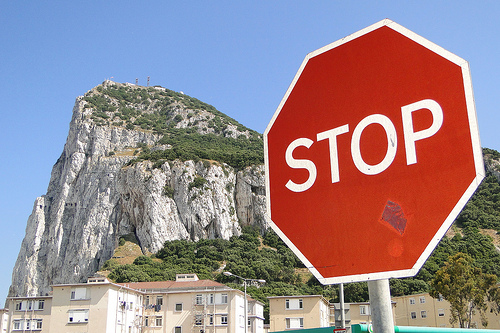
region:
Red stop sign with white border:
[260, 11, 490, 315]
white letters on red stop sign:
[282, 87, 449, 194]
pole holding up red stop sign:
[353, 261, 426, 331]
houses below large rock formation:
[5, 273, 310, 330]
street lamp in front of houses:
[221, 263, 271, 331]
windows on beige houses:
[63, 285, 100, 323]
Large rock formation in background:
[7, 69, 259, 257]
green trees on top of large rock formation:
[157, 133, 251, 160]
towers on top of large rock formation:
[112, 73, 154, 89]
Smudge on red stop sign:
[372, 191, 415, 242]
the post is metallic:
[362, 288, 400, 332]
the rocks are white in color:
[81, 156, 131, 218]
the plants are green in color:
[240, 230, 260, 282]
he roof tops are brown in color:
[178, 272, 215, 286]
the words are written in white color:
[286, 117, 426, 193]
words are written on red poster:
[284, 95, 448, 191]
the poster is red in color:
[287, 91, 452, 254]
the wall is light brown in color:
[98, 299, 115, 331]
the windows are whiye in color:
[291, 298, 308, 312]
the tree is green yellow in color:
[445, 264, 490, 308]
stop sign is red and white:
[264, 22, 484, 279]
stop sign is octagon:
[261, 18, 488, 283]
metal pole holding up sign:
[368, 274, 393, 331]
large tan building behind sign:
[8, 270, 495, 332]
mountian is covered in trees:
[4, 80, 499, 320]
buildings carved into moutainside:
[34, 193, 81, 221]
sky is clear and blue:
[1, 1, 498, 307]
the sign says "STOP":
[268, 96, 443, 195]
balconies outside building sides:
[8, 282, 229, 332]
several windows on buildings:
[13, 288, 499, 330]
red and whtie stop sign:
[236, 21, 483, 301]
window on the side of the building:
[171, 300, 186, 314]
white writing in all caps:
[276, 92, 448, 207]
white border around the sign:
[232, 18, 490, 288]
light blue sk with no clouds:
[1, 0, 498, 310]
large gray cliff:
[4, 49, 293, 309]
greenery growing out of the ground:
[65, 75, 277, 182]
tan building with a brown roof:
[2, 271, 257, 331]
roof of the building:
[52, 264, 239, 299]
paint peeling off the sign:
[369, 196, 418, 238]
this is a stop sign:
[322, 91, 482, 248]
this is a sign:
[284, 125, 396, 245]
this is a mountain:
[65, 119, 226, 229]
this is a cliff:
[105, 51, 200, 267]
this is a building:
[92, 219, 243, 331]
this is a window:
[195, 301, 227, 327]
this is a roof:
[123, 252, 160, 285]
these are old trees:
[169, 259, 241, 288]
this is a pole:
[360, 256, 422, 330]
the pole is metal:
[342, 302, 374, 323]